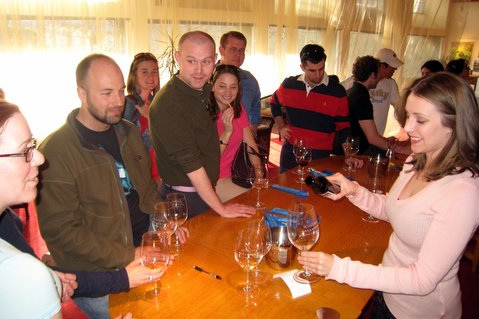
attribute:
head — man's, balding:
[76, 53, 125, 123]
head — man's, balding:
[175, 30, 218, 89]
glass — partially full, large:
[286, 202, 320, 284]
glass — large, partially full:
[234, 227, 264, 310]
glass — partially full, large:
[141, 231, 172, 306]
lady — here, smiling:
[298, 72, 479, 319]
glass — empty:
[293, 138, 311, 182]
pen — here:
[193, 266, 223, 280]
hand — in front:
[223, 200, 257, 219]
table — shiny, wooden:
[109, 141, 413, 318]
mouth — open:
[408, 134, 423, 145]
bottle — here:
[295, 169, 344, 198]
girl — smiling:
[210, 64, 269, 204]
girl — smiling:
[119, 51, 168, 229]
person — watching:
[0, 102, 77, 318]